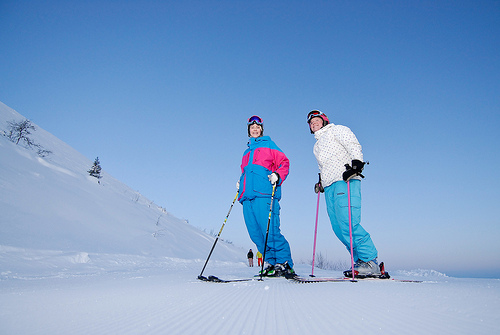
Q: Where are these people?
A: A ski mountain.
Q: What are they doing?
A: Skiing.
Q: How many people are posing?
A: Two.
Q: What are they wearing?
A: Ski clothing.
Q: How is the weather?
A: Blue skies and sunny.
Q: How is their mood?
A: Happy.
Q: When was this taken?
A: During the day.